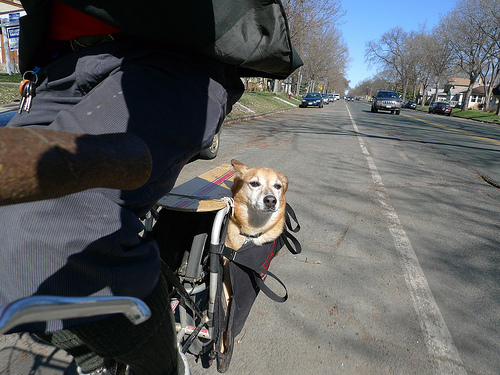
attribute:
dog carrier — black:
[215, 233, 299, 351]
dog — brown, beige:
[222, 159, 292, 249]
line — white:
[334, 98, 479, 368]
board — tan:
[161, 146, 251, 233]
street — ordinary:
[318, 82, 469, 373]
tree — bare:
[435, 1, 499, 112]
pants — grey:
[0, 66, 229, 367]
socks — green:
[54, 328, 110, 374]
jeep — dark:
[371, 87, 406, 119]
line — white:
[336, 149, 457, 328]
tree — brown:
[360, 17, 468, 118]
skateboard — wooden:
[147, 122, 308, 247]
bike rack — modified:
[161, 147, 321, 352]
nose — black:
[263, 193, 276, 206]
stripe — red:
[166, 161, 249, 208]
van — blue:
[364, 83, 407, 117]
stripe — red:
[168, 163, 245, 214]